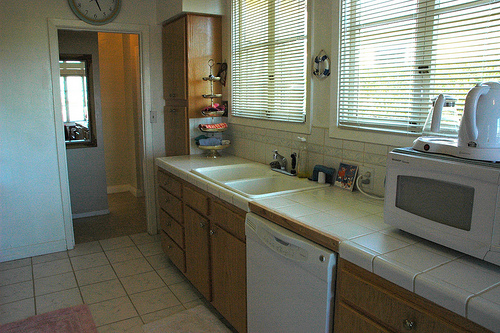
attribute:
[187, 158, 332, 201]
sink — porcelain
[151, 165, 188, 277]
drawers — brown 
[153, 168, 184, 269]
drawers — closed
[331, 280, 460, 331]
drawers — closed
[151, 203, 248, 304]
cabinets — bottom, brown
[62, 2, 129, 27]
clock — white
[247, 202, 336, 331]
dishwasher — white 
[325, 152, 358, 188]
picture — framed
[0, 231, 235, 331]
floor — tiled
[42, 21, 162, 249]
door — open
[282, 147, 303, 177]
faucet — black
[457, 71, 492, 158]
coffee maker — white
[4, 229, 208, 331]
floor — tiled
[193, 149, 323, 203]
sink — kitchen, double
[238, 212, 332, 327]
dishwasher — recessed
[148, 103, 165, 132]
switch — light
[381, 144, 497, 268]
microwave — white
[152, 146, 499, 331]
counter — tiled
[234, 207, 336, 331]
dishwasher — large, white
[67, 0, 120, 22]
clock — circular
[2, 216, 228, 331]
floor — tiled